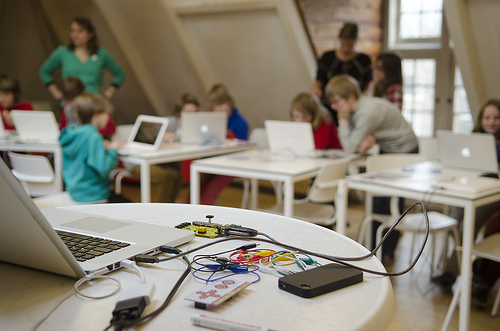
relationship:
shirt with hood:
[58, 121, 118, 201] [59, 120, 94, 157]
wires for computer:
[113, 194, 443, 321] [4, 143, 187, 293]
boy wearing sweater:
[326, 76, 437, 174] [335, 95, 417, 154]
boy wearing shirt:
[56, 88, 119, 203] [58, 123, 118, 203]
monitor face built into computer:
[133, 121, 162, 145] [116, 114, 170, 156]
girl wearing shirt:
[45, 14, 110, 81] [378, 82, 404, 115]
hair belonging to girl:
[372, 50, 402, 97] [45, 14, 110, 81]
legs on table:
[189, 164, 347, 227] [184, 140, 348, 222]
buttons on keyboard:
[51, 221, 132, 261] [35, 174, 125, 287]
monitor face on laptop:
[133, 121, 162, 145] [113, 109, 181, 162]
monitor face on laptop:
[133, 121, 162, 145] [172, 100, 240, 147]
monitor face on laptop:
[133, 121, 162, 145] [250, 104, 332, 164]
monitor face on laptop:
[133, 121, 162, 145] [428, 119, 498, 184]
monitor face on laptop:
[133, 121, 162, 145] [5, 96, 67, 150]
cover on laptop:
[0, 152, 85, 276] [32, 204, 197, 269]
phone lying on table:
[273, 257, 370, 300] [258, 294, 330, 329]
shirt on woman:
[34, 44, 119, 109] [38, 4, 165, 106]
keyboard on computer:
[50, 227, 130, 261] [0, 156, 195, 281]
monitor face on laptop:
[130, 119, 165, 144] [120, 102, 173, 163]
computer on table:
[0, 156, 195, 281] [0, 192, 398, 330]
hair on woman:
[60, 13, 105, 63] [35, 18, 131, 111]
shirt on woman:
[36, 44, 125, 108] [35, 18, 131, 111]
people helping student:
[313, 21, 374, 127] [365, 38, 409, 118]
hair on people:
[323, 22, 364, 58] [313, 21, 374, 127]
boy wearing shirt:
[57, 93, 135, 204] [64, 125, 114, 200]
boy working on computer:
[57, 93, 135, 204] [112, 112, 178, 166]